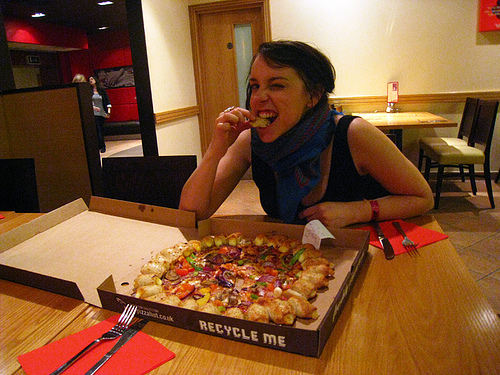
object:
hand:
[207, 105, 257, 154]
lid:
[0, 194, 195, 302]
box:
[0, 194, 372, 362]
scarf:
[250, 97, 340, 222]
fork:
[390, 220, 419, 250]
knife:
[373, 224, 396, 260]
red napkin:
[350, 219, 448, 256]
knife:
[76, 320, 152, 375]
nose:
[252, 86, 269, 104]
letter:
[206, 321, 215, 334]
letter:
[214, 322, 225, 336]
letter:
[223, 326, 233, 338]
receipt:
[298, 219, 338, 251]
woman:
[177, 38, 435, 228]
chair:
[428, 99, 497, 210]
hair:
[240, 38, 335, 101]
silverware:
[83, 315, 151, 374]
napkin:
[14, 313, 175, 375]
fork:
[50, 302, 136, 375]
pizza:
[130, 230, 335, 329]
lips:
[256, 109, 278, 117]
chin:
[254, 126, 279, 145]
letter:
[197, 320, 205, 332]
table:
[350, 95, 458, 152]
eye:
[250, 79, 263, 92]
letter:
[275, 334, 289, 348]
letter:
[261, 331, 279, 347]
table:
[0, 209, 499, 374]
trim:
[156, 105, 203, 126]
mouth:
[249, 107, 280, 131]